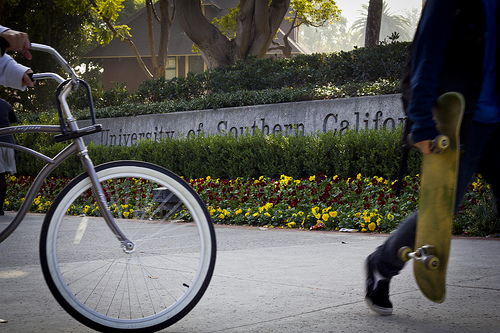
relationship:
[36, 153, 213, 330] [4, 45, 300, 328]
tire of bicycle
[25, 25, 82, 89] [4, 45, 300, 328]
handle of bicycle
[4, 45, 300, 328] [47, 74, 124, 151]
bicycle has lock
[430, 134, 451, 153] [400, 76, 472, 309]
wheels on skateboard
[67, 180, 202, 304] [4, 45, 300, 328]
spokes on bicycle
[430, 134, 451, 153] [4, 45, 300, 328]
wheels on bicycle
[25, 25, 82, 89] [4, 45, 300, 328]
bar on bicycle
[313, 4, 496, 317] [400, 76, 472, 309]
person carrying skateboard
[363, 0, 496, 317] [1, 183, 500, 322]
person on sidewalk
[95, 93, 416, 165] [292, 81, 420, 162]
signs says california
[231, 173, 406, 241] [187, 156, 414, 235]
flowers in background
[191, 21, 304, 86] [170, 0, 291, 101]
trunk of trunk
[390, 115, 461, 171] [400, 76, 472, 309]
wheels on skateboard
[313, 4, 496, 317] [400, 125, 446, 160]
person has hands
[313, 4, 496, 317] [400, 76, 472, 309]
person holding skateboard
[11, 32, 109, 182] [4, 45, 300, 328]
person on bike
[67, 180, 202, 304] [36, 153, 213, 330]
spokes on tire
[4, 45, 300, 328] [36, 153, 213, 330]
bike has tire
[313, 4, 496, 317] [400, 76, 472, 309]
person has skateboard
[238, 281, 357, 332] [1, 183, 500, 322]
crack in sidewalk